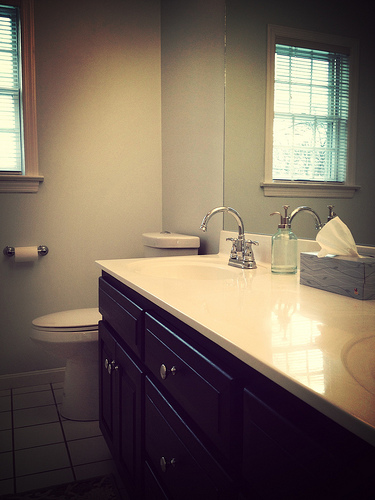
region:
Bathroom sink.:
[97, 164, 266, 286]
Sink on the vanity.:
[197, 188, 266, 275]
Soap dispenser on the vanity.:
[265, 186, 318, 311]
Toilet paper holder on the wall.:
[2, 236, 90, 277]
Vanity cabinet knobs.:
[105, 342, 125, 379]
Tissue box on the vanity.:
[283, 196, 364, 297]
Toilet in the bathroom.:
[18, 206, 166, 453]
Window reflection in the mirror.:
[261, 17, 346, 221]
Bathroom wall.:
[64, 153, 103, 209]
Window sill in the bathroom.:
[7, 169, 68, 185]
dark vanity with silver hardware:
[91, 247, 351, 476]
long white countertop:
[84, 228, 361, 408]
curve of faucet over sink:
[184, 195, 259, 285]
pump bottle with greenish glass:
[258, 190, 308, 280]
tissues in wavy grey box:
[290, 210, 365, 306]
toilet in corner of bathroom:
[30, 215, 210, 406]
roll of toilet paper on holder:
[3, 227, 48, 267]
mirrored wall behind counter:
[207, 18, 363, 269]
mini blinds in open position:
[250, 40, 356, 197]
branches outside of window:
[270, 41, 338, 187]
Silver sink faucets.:
[178, 195, 263, 284]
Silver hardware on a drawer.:
[139, 359, 189, 394]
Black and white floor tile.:
[0, 403, 78, 473]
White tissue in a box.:
[299, 206, 365, 303]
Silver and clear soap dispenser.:
[247, 199, 299, 304]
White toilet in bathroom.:
[0, 216, 189, 417]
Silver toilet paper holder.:
[0, 226, 62, 268]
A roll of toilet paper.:
[10, 238, 48, 275]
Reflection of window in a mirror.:
[264, 104, 358, 211]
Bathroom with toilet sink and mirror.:
[16, 126, 366, 484]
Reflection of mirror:
[253, 14, 362, 202]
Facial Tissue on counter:
[297, 213, 373, 306]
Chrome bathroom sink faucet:
[195, 199, 260, 276]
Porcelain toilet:
[26, 225, 205, 426]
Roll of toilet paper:
[0, 233, 54, 269]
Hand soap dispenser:
[263, 203, 304, 280]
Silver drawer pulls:
[97, 354, 188, 481]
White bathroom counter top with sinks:
[90, 223, 371, 442]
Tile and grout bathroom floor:
[0, 379, 139, 495]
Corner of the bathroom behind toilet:
[134, 1, 184, 231]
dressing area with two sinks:
[96, 256, 372, 430]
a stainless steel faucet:
[194, 197, 261, 278]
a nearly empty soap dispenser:
[261, 201, 301, 279]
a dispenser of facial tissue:
[297, 214, 373, 297]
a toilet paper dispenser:
[1, 236, 54, 267]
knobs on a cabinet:
[95, 355, 122, 379]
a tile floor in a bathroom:
[7, 385, 100, 493]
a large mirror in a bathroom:
[222, 0, 374, 244]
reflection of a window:
[263, 29, 356, 197]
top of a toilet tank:
[138, 224, 203, 256]